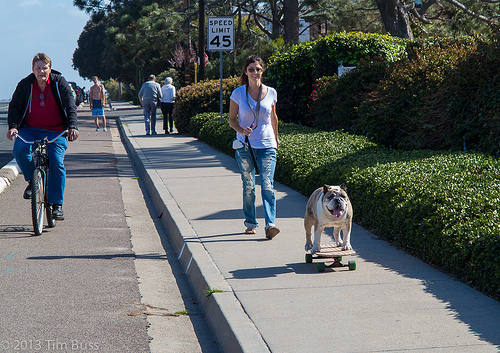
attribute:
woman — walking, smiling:
[228, 55, 280, 239]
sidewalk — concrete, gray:
[108, 94, 498, 350]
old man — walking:
[138, 72, 164, 137]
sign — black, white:
[207, 16, 236, 52]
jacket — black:
[6, 69, 78, 129]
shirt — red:
[23, 78, 66, 133]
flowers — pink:
[168, 44, 198, 67]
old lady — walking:
[159, 77, 179, 134]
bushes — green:
[173, 30, 499, 297]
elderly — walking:
[139, 73, 176, 135]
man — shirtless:
[89, 75, 107, 132]